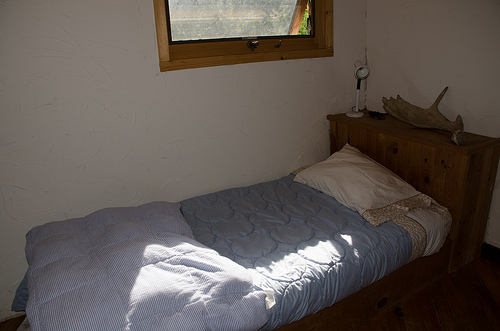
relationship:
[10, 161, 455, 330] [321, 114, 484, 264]
bed has headboard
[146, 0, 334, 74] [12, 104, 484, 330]
window above bed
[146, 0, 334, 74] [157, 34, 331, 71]
window has frame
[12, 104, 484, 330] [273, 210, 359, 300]
bed has blanket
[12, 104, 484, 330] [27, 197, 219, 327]
bed has blanket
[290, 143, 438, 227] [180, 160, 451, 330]
pillow match bed-cover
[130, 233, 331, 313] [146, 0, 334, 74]
light coming through window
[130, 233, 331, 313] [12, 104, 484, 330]
light shining on bed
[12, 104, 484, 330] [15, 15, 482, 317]
bed in room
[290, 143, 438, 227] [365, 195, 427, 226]
pillow has leopard pattern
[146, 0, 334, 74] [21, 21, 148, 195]
window on wall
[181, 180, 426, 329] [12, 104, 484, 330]
bed-cover on bed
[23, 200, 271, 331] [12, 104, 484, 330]
blanket on bed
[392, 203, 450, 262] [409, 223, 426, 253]
white sheet has leopard pattern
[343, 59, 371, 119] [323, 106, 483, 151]
lamp on top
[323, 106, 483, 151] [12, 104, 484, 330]
top of bed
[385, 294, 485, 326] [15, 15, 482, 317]
floor in room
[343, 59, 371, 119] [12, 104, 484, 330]
lamp on bed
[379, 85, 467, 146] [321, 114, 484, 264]
antler on headboard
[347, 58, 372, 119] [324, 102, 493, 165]
lamp on headboard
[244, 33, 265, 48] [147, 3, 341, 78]
handle on window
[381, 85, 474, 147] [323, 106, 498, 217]
antler on headboard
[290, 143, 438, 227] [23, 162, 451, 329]
pillow on bed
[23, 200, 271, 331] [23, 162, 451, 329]
blanket on bed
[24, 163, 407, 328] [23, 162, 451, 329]
blanket on bed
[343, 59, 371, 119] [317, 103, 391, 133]
lamp on shelf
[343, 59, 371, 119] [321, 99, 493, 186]
lamp on shelf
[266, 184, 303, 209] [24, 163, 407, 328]
circle on blanket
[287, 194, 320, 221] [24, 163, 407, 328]
circle on blanket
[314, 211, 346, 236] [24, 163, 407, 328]
circle on blanket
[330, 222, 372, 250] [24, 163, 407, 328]
circle on blanket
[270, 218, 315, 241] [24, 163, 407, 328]
circle on blanket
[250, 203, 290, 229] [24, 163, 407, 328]
circle on blanket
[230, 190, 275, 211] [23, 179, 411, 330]
circle on blanket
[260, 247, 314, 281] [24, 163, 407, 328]
circle on blanket